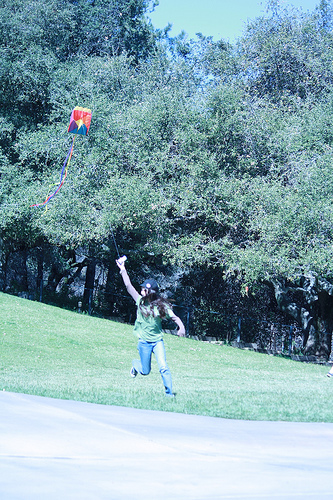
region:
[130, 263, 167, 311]
the head of a person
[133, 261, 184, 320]
the hair of a person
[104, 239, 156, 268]
the hand of a person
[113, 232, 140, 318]
the arm of a person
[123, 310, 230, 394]
the legs of a person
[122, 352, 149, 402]
the foot of a person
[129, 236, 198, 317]
a person wearing a hat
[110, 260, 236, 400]
a person standing on the grass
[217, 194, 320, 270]
trees with green leaves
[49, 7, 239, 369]
a person flying a kite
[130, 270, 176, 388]
the girl is running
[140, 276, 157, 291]
the hat is blue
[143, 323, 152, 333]
the shirt is green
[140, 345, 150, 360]
the pants are blue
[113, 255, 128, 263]
she is holding the handle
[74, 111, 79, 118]
the piece is red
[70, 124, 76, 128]
the piece is purple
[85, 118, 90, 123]
the piece is orange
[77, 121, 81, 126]
the piece is yellow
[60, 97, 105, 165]
the kite is in the air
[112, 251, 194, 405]
girl running in the grass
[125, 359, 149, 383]
back foot lifted off the ground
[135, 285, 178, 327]
hair is blowing in the wind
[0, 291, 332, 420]
green grass on the ground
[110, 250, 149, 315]
arm is lifted up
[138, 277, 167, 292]
hat on top of the head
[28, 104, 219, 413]
girl flying a kite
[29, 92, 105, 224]
red, blue, and yellow kite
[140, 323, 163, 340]
wrinkles on the shirt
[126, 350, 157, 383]
leg is bent at the knee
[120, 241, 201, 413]
this is a lady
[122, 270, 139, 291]
the lady is light skinned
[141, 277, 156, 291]
this is a cap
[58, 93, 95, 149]
this is a kite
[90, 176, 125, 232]
this is a string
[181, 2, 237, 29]
this is the sky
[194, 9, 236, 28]
the sky is blue in color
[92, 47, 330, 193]
this s a forest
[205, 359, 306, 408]
this is a grass area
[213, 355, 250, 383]
the grass is green in color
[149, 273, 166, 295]
This person is wearing a navy-colored hat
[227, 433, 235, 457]
There is a patch of black asphalt here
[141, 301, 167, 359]
This person is wearing a green t-shirt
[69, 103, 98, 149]
This person is flying a multi-colored kite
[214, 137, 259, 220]
There are dark green trees in the distance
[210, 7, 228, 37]
There is a light blue sky that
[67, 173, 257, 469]
Jackson Mingus took this photo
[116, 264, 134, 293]
This person is wearing a wrist watch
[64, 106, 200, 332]
This photo was taken in the city of Phoenix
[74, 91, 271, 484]
This photo was taken in the state of Arizona